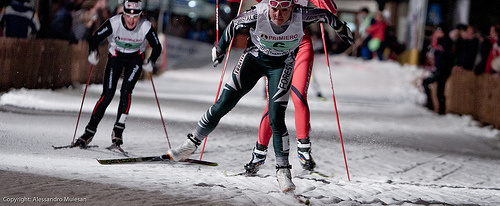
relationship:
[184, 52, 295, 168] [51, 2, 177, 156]
pants on athlete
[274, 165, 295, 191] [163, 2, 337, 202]
boot of skier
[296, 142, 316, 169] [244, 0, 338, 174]
boot of man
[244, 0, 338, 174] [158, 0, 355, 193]
man wearing man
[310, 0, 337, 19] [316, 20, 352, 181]
flag on top of pole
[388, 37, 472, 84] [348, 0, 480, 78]
fence in front of people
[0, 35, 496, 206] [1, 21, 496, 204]
ground on ground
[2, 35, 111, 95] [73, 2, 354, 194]
wooden fence in front of people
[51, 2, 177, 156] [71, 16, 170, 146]
athlete in outfit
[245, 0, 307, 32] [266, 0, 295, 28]
goggles on person's face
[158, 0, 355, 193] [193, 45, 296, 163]
man with pants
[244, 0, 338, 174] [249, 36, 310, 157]
man with pants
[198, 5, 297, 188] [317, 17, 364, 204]
man holding ski pole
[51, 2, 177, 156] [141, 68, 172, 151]
athlete holding ski pole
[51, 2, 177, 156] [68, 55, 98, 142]
athlete holding ski pole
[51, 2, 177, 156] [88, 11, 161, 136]
athlete wearing uniform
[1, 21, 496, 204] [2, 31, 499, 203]
ground covered in snow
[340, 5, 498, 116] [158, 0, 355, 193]
crowd watching man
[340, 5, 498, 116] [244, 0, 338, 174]
crowd watching man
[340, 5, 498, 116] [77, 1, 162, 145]
crowd watching skier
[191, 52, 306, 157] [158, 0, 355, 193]
pants on man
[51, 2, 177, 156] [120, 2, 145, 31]
athlete has head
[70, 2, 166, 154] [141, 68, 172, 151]
athlete has ski pole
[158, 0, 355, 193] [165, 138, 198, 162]
man has boot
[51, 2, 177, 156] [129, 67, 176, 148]
athlete has ski pole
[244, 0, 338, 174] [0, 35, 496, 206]
man on ground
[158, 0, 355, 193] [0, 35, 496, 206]
man on ground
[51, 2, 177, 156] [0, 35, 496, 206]
athlete on ground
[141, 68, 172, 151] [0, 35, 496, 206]
ski pole on ground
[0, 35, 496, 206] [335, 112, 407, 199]
ground on ground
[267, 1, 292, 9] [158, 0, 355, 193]
goggles on man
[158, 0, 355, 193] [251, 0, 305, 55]
man wears vest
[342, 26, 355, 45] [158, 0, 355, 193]
glove on man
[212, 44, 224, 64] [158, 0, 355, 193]
glove on man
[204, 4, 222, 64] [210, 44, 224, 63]
pole on glove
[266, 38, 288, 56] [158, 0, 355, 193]
number on man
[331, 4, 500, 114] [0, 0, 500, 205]
crowd watch ski race